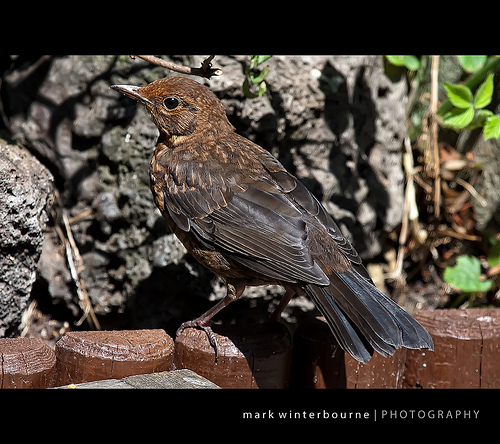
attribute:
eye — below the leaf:
[162, 98, 183, 109]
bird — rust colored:
[103, 73, 437, 366]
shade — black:
[218, 308, 330, 386]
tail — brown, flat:
[309, 277, 436, 356]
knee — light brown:
[225, 281, 247, 301]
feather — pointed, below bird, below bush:
[344, 335, 447, 364]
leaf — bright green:
[249, 54, 272, 94]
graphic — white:
[240, 401, 489, 433]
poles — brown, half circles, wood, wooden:
[2, 302, 499, 384]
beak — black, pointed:
[110, 81, 143, 97]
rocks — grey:
[0, 157, 48, 332]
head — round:
[109, 76, 235, 137]